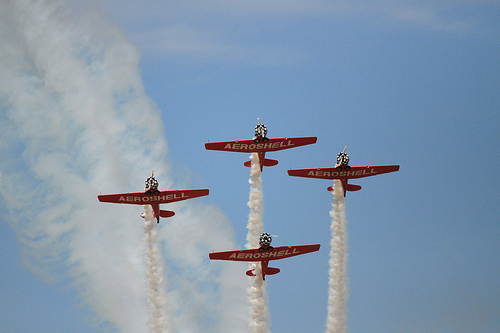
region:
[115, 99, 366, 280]
Four plains flying in formation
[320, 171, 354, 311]
A smoke trail behind a plane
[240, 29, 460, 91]
A beautiful blue sky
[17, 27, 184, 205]
A large white cloud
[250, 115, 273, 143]
The spinning propeller on a plane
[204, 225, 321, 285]
A plane flying through another plane's smoke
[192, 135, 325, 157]
A plane's wings showing the name AEROSHELL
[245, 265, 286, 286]
The tail of a red airplane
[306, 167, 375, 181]
White letters on the wings of a plane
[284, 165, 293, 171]
An antenna on the tip of a plane's wing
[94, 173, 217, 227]
a plane in the sky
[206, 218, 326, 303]
a plane in the sky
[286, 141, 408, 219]
a plane in the sky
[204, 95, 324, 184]
a plane in the sky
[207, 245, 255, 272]
the wing of a plane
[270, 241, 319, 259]
the wing of a plane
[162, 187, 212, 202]
the wing of a plane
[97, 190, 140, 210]
the wing of a plane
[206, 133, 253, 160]
the wing of a plane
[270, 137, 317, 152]
the wing of a plane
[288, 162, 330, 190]
the wing of a plane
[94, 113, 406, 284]
The four planes in the sky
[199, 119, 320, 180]
The plane in the lead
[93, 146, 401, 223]
The two middle planes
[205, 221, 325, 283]
The plane in the back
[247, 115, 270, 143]
The propeller of the lead plane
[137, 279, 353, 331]
The trails of all four planes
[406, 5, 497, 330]
The open sky on the right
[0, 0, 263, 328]
The clouds on the left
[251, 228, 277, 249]
The propeller of the last train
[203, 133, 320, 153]
The wings of the led train